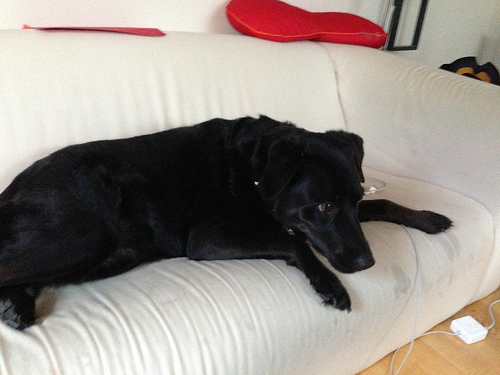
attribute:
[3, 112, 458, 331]
dog — black, laying, here, large, laying down, resting, liking'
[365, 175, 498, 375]
charger — white, computer's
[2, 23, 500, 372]
couch — white, solid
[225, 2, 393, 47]
pillow — red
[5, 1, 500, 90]
wall — white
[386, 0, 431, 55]
frame — mirror's, black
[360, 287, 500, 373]
floor — wood, brown, light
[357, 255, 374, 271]
nose — dog's, black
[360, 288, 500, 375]
wood — brown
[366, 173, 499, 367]
wire — electrical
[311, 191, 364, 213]
eyes — open, brown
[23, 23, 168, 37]
item — pink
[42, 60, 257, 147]
row — wrinkles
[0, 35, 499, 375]
fabric — couch's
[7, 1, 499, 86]
walls — white, solid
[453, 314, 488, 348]
box — white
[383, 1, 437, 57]
mirror — black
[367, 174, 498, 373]
cord — white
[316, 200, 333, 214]
eye — brown